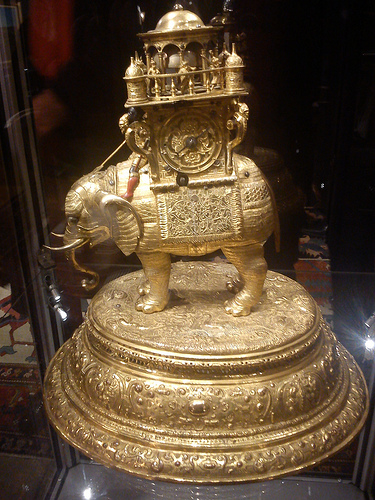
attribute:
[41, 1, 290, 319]
elephant — metal, shiny, statue, gold, golden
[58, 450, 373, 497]
surface — shiny, grey, brown, long, hidden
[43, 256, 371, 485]
bottom — round, shiny, brown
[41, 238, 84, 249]
tusk — grey, gold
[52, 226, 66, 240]
tusk — grey, gold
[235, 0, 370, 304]
surface — black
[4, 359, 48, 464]
mat — flower colored, area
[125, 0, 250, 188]
model — city, tall, beautiful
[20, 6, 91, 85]
object — wide, red, hanging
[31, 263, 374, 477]
statue — gold, golden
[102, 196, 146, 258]
ear — gold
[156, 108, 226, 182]
clock — gold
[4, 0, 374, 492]
case — glass, display, clear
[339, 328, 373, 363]
spotlight — white, reflected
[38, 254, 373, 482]
dome — gold, bell shaped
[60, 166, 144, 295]
head — gold, golden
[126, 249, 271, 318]
feet — gold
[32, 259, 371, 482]
base — gold, round, golden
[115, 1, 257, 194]
decoration — large, gold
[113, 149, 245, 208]
back — elephant's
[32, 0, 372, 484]
decoration — gold, elephant, ornate, large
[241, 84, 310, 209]
reflection — elephant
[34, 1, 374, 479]
statue — gold, elephant, golden, thai, metal, decorative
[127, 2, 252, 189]
building — golden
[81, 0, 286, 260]
details — decorative, gold